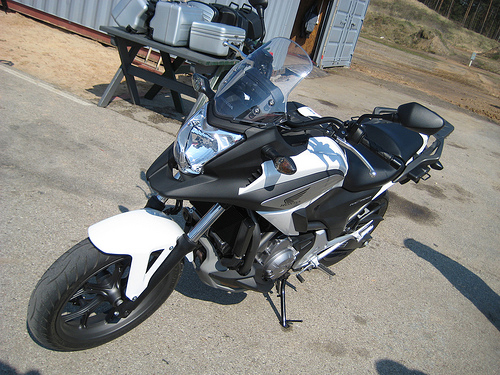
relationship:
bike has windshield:
[25, 36, 455, 351] [213, 34, 313, 126]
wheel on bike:
[26, 236, 185, 351] [25, 36, 455, 351]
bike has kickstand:
[25, 36, 455, 351] [278, 270, 293, 328]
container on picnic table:
[110, 0, 154, 38] [94, 23, 237, 119]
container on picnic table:
[148, 0, 201, 50] [94, 23, 237, 119]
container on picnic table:
[188, 20, 247, 59] [94, 23, 237, 119]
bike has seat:
[25, 36, 455, 351] [330, 120, 423, 192]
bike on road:
[25, 36, 455, 351] [1, 63, 500, 373]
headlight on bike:
[174, 104, 243, 176] [25, 36, 455, 351]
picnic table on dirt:
[94, 23, 237, 119] [1, 9, 170, 99]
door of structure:
[284, 0, 332, 66] [1, 1, 368, 70]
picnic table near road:
[94, 23, 237, 119] [1, 63, 500, 373]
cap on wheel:
[86, 205, 186, 302] [26, 236, 185, 351]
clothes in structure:
[299, 2, 319, 37] [1, 1, 368, 70]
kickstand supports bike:
[278, 270, 293, 328] [25, 36, 455, 351]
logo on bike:
[281, 185, 311, 208] [25, 36, 455, 351]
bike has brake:
[25, 36, 455, 351] [223, 41, 251, 65]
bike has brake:
[25, 36, 455, 351] [331, 135, 376, 177]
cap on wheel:
[86, 205, 186, 302] [25, 207, 184, 353]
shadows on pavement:
[1, 200, 498, 373] [6, 58, 497, 369]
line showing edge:
[0, 57, 91, 110] [26, 70, 73, 97]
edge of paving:
[26, 70, 73, 97] [1, 60, 497, 372]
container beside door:
[312, 8, 367, 72] [253, 10, 303, 57]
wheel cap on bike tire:
[99, 278, 126, 312] [27, 236, 191, 354]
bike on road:
[25, 36, 455, 351] [2, 66, 149, 208]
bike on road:
[25, 36, 455, 351] [166, 295, 496, 373]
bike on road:
[25, 36, 455, 351] [391, 183, 496, 290]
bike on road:
[25, 36, 455, 351] [301, 79, 403, 106]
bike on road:
[25, 36, 455, 351] [455, 108, 499, 155]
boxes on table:
[102, 0, 247, 59] [100, 22, 240, 121]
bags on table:
[218, 9, 265, 41] [110, 24, 242, 119]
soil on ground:
[0, 10, 123, 94] [1, 10, 499, 373]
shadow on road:
[401, 236, 498, 333] [1, 63, 500, 373]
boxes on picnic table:
[102, 0, 247, 59] [94, 23, 237, 119]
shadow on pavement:
[401, 236, 498, 333] [6, 58, 497, 369]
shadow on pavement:
[368, 353, 429, 373] [6, 58, 497, 369]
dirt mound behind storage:
[370, 11, 437, 56] [0, 0, 368, 67]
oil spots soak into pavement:
[319, 325, 375, 359] [400, 279, 448, 324]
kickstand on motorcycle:
[278, 270, 293, 328] [24, 36, 456, 354]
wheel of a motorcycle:
[26, 236, 185, 351] [24, 36, 456, 354]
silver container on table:
[108, 1, 152, 34] [103, 22, 241, 132]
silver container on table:
[150, 0, 204, 46] [103, 22, 241, 132]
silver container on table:
[185, 18, 249, 58] [103, 22, 241, 132]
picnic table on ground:
[94, 23, 237, 119] [1, 10, 499, 373]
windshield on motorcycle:
[213, 34, 313, 126] [24, 36, 456, 354]